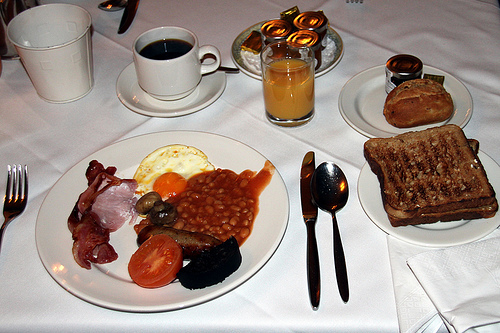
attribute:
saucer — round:
[111, 77, 226, 117]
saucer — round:
[115, 49, 277, 111]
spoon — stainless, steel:
[319, 162, 360, 299]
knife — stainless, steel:
[293, 142, 328, 309]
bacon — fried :
[67, 173, 132, 274]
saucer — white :
[355, 165, 388, 237]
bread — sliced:
[403, 143, 456, 190]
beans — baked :
[198, 167, 265, 227]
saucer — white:
[341, 66, 387, 138]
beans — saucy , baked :
[181, 167, 261, 233]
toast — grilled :
[354, 131, 495, 223]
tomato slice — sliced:
[129, 234, 186, 287]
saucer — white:
[112, 66, 231, 123]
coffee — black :
[139, 39, 193, 59]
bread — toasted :
[365, 124, 497, 229]